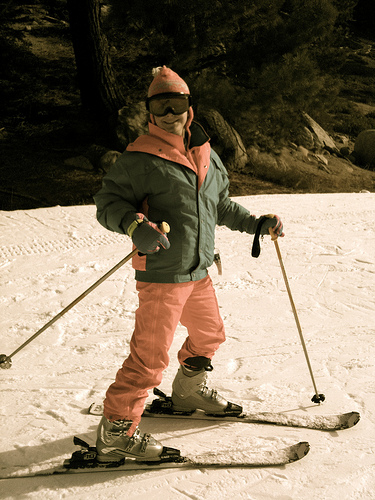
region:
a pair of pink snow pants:
[100, 276, 225, 425]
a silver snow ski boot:
[94, 417, 162, 463]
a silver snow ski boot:
[169, 363, 230, 413]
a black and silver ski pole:
[3, 220, 171, 376]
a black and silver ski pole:
[265, 212, 327, 402]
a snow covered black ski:
[4, 439, 308, 481]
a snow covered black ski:
[88, 394, 361, 434]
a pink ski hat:
[147, 64, 191, 97]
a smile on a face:
[161, 116, 181, 124]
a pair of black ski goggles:
[144, 90, 191, 116]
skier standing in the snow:
[29, 73, 348, 446]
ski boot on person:
[70, 410, 181, 466]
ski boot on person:
[171, 357, 238, 419]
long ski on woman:
[19, 448, 309, 476]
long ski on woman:
[196, 392, 351, 430]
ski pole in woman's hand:
[263, 234, 326, 413]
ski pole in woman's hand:
[12, 260, 135, 369]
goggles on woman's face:
[146, 94, 192, 120]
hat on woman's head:
[131, 61, 185, 101]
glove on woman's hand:
[131, 220, 173, 254]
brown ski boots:
[60, 398, 209, 479]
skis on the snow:
[18, 379, 352, 497]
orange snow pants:
[100, 258, 244, 438]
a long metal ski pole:
[0, 203, 183, 376]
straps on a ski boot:
[125, 429, 158, 450]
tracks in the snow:
[25, 218, 73, 281]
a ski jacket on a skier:
[80, 132, 275, 304]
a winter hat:
[136, 49, 199, 108]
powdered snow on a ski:
[242, 403, 352, 438]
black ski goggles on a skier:
[120, 72, 215, 134]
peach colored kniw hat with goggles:
[140, 57, 195, 136]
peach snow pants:
[103, 277, 230, 420]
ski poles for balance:
[0, 221, 341, 409]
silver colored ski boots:
[79, 367, 249, 465]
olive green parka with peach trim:
[95, 133, 266, 284]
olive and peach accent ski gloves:
[116, 208, 171, 259]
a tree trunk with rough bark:
[50, 6, 142, 136]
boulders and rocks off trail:
[208, 82, 359, 184]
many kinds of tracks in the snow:
[1, 199, 97, 464]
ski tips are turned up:
[208, 372, 370, 482]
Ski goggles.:
[140, 88, 199, 118]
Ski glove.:
[113, 181, 174, 264]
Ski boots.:
[91, 356, 241, 481]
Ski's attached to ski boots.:
[1, 374, 366, 490]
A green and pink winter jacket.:
[84, 120, 282, 290]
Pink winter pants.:
[97, 250, 238, 439]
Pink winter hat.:
[130, 59, 224, 153]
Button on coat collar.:
[201, 160, 209, 177]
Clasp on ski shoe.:
[105, 412, 158, 451]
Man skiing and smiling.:
[68, 36, 291, 489]